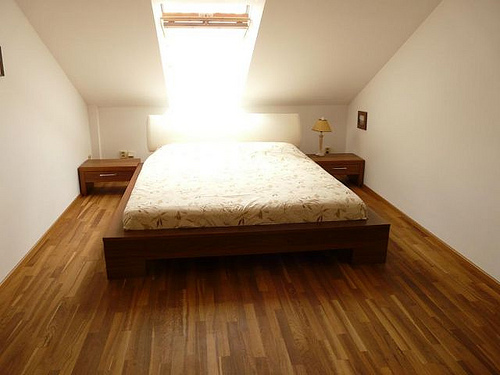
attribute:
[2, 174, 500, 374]
floor — wooden, brown, hardwood, wood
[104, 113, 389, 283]
bed — wooden, made, brown wooden, brown, full mattress, wooden framed, wood, large, white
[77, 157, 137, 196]
nightstand — empty, bare, brown, wooden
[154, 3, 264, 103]
skylight — open, large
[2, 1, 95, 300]
wall — white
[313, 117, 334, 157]
lamp — off, beige, gold, yellow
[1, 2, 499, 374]
bedroom — large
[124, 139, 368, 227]
bedspread — light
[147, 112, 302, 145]
headboard — white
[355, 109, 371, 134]
picture — red, small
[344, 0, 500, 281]
wall — white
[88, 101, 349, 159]
wall — white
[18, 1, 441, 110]
ceiling — white, slanted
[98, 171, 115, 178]
handle — silver